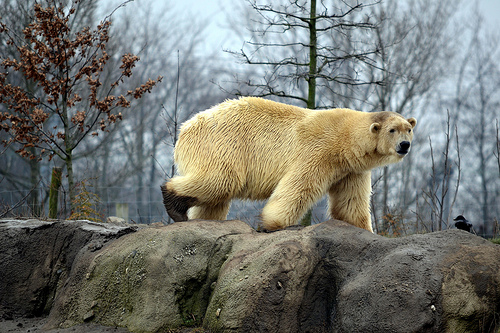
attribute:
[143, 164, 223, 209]
paws — dark, brown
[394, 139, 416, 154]
nose — black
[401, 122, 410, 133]
eyes — black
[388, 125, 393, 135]
eyes — black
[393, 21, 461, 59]
sky — gray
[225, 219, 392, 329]
rock — grey, large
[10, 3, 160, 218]
tree — large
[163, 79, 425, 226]
bear — large, light, brown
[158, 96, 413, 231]
bear — brown, white, tan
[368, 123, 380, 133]
ear — white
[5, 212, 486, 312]
rocks — grey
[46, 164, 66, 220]
post — wooden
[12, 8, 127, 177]
leaves — brown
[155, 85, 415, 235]
polar bear — large, white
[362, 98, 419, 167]
head — white, black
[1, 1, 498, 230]
sky — blue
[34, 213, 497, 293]
boulder — large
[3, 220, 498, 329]
wall — gray, rock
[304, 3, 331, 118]
tree — small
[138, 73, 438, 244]
bear — polar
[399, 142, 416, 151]
nose — dark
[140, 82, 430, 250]
polar bear — white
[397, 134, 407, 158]
nose — black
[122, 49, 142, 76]
leaves — brown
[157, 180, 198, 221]
paw — black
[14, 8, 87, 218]
tree — small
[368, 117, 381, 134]
ears — white